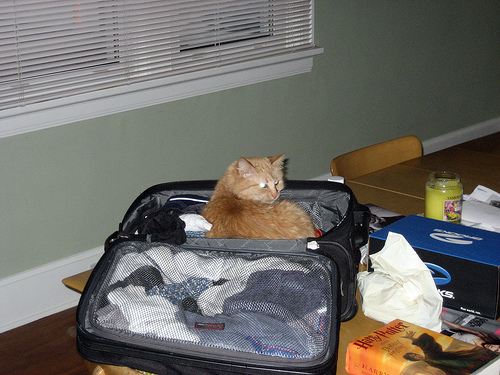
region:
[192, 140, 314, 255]
the cat is in a case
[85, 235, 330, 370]
the flap of a suitcase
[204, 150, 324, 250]
this is a brown cat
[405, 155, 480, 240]
this is petroleum jelly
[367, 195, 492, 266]
this is a blue folder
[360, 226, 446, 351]
this is a white cloth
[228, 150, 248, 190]
the ear of a cat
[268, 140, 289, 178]
the ear of a cat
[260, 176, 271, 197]
the eye of a cat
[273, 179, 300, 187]
the eye of a cat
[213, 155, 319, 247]
long haired orange cat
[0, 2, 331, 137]
white plastic window blinds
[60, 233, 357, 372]
opened packed black suitcase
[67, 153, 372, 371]
orange cat sitting in suitcase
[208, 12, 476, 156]
gray colored indoor wall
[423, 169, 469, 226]
yellow scented candle inside jar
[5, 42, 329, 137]
white window sill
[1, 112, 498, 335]
white baseboard along olive colored wall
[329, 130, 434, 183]
wood chair pushed under table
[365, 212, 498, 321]
black and blue shoe box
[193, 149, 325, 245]
Orange cat turning its head.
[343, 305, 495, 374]
Harry Potter book on table.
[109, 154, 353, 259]
Cat sitting inside suitcase.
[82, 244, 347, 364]
Suitcase filled with clothes.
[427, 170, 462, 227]
Yellow candle on table.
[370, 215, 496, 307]
Black, blue and white shoe box.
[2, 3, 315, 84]
Slats of white blinds are open.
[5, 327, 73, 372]
Brown wooden floor.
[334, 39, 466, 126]
Green painted wall.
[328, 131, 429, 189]
Brown chair tucked under table.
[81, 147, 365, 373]
cat in a black suticase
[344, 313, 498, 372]
Harry Potter hardcover book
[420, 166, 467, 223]
yellow jar candle on table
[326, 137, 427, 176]
back of wood chair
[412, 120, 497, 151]
white baseboard against wood floor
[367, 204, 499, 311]
Brooks black and blue shoebox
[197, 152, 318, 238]
cat with glowing eyes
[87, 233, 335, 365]
clothes packed in zippered mesh compartment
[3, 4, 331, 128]
windows with mini blinds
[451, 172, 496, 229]
papers on table under candle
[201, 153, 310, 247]
orange cat laying in the suitcase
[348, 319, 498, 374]
harry potter and the deathly hallows hardback book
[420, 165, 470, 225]
yellow candle in glass jar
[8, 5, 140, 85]
white blinds in the window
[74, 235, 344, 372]
open suitcase with full mesh side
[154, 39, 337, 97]
white wood window sill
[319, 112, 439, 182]
back of wooden chair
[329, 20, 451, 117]
green wall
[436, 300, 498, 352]
magazine laying on the table